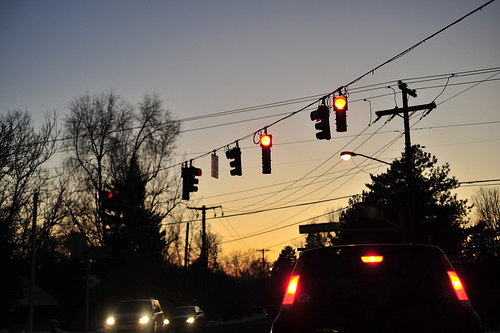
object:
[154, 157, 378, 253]
sun setting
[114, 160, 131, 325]
pole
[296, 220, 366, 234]
street sign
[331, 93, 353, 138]
light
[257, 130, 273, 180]
light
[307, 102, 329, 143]
light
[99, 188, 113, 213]
light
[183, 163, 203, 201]
light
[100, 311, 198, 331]
headlights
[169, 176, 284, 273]
pole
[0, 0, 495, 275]
sky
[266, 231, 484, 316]
brakelights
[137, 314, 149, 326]
car light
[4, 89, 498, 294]
trees line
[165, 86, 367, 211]
traffic lights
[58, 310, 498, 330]
street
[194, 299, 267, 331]
snow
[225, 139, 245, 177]
traffic light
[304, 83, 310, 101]
wall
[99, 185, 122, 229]
red light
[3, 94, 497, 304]
trees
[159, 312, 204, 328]
motorcycles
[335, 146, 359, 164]
light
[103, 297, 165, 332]
car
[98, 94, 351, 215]
lights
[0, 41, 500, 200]
wire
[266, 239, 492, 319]
suv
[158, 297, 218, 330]
car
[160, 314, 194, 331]
head lights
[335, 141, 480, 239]
tree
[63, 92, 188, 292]
tree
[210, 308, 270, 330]
road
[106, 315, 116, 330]
head light